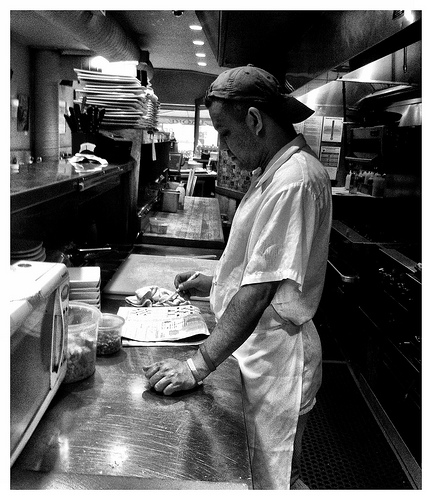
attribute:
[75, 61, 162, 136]
trays — stack , empty 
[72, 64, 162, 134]
plates — stack 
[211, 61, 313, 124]
cap — worn, here, black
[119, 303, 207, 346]
page — folded, here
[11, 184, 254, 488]
counter — aluminum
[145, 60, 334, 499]
worker — here, light skinned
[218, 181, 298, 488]
apron — white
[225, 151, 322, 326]
shirt — here, white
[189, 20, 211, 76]
lighting fixtures — overhead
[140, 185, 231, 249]
table — wooden, here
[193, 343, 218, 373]
wrist band — here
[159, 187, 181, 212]
tin — here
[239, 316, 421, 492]
ground — here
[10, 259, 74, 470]
microwave — here, white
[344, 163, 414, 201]
bottles — plastic